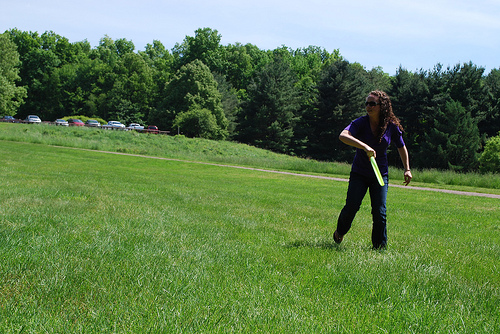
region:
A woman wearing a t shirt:
[332, 90, 410, 249]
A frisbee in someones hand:
[370, 153, 385, 187]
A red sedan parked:
[70, 118, 83, 126]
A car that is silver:
[27, 113, 41, 124]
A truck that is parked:
[126, 122, 145, 129]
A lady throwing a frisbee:
[333, 88, 411, 249]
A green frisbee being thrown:
[370, 155, 385, 187]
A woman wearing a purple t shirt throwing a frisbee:
[331, 90, 411, 251]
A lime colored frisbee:
[370, 156, 385, 186]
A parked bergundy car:
[145, 123, 159, 133]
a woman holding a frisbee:
[331, 84, 414, 251]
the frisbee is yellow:
[367, 154, 387, 187]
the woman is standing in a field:
[1, 90, 498, 330]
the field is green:
[1, 138, 494, 331]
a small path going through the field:
[33, 136, 497, 219]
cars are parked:
[3, 106, 161, 137]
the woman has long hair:
[362, 89, 403, 136]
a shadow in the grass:
[278, 228, 337, 253]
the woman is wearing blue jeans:
[331, 165, 394, 245]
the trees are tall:
[0, 25, 499, 176]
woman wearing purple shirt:
[329, 83, 420, 257]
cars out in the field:
[22, 110, 169, 134]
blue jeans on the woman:
[332, 171, 392, 256]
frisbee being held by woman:
[365, 148, 385, 189]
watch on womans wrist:
[394, 165, 416, 173]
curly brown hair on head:
[380, 93, 397, 125]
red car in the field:
[70, 117, 80, 124]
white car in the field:
[108, 118, 123, 130]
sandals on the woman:
[330, 228, 343, 243]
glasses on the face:
[362, 97, 380, 113]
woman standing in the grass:
[323, 78, 435, 261]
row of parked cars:
[5, 102, 157, 136]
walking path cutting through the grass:
[119, 136, 499, 216]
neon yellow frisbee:
[368, 154, 394, 188]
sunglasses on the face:
[362, 97, 382, 110]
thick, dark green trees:
[0, 13, 499, 163]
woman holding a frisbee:
[321, 81, 428, 266]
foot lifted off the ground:
[327, 227, 342, 249]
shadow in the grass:
[269, 221, 350, 263]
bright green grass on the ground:
[2, 122, 494, 327]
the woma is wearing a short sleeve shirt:
[345, 110, 407, 162]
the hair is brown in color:
[365, 87, 398, 127]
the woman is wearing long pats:
[344, 161, 391, 240]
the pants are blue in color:
[335, 160, 396, 246]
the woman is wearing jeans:
[338, 165, 390, 240]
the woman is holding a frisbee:
[341, 120, 389, 195]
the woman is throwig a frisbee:
[343, 128, 385, 189]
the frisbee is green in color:
[367, 152, 390, 187]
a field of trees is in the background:
[0, 28, 497, 188]